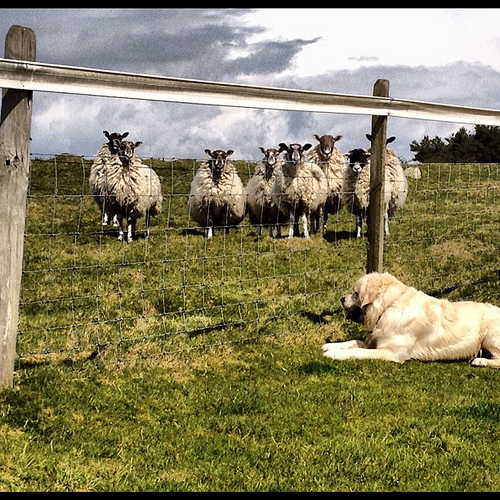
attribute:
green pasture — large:
[3, 138, 498, 492]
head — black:
[95, 134, 133, 151]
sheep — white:
[76, 139, 138, 210]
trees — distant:
[430, 134, 454, 159]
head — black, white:
[312, 132, 343, 160]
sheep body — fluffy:
[306, 145, 346, 214]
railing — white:
[1, 57, 498, 126]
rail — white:
[13, 49, 480, 151]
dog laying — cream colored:
[318, 265, 499, 390]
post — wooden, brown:
[316, 122, 401, 266]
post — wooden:
[0, 22, 40, 392]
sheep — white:
[343, 149, 405, 235]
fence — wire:
[5, 20, 498, 385]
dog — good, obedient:
[318, 268, 498, 362]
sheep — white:
[75, 121, 130, 189]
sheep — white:
[113, 133, 159, 198]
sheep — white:
[182, 141, 258, 228]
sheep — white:
[252, 136, 303, 213]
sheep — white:
[311, 126, 357, 190]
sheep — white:
[181, 124, 248, 247]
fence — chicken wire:
[32, 158, 222, 325]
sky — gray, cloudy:
[2, 6, 497, 170]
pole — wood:
[8, 11, 38, 386]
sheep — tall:
[184, 147, 249, 243]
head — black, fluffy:
[339, 128, 394, 203]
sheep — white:
[314, 114, 449, 246]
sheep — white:
[87, 128, 407, 241]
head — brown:
[315, 135, 341, 162]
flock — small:
[86, 115, 412, 252]